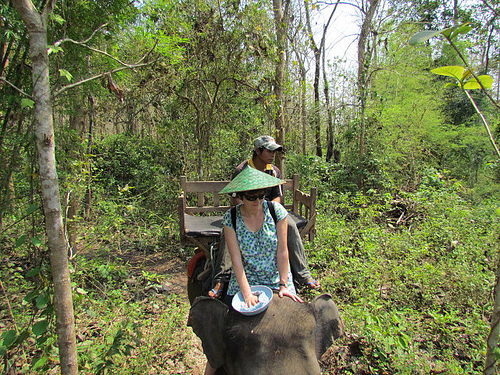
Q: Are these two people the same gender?
A: No, they are both male and female.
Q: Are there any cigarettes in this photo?
A: No, there are no cigarettes.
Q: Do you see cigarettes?
A: No, there are no cigarettes.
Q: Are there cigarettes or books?
A: No, there are no cigarettes or books.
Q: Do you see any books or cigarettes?
A: No, there are no cigarettes or books.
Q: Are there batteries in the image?
A: No, there are no batteries.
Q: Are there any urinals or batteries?
A: No, there are no batteries or urinals.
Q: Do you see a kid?
A: No, there are no children.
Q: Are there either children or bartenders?
A: No, there are no children or bartenders.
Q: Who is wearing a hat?
A: The man is wearing a hat.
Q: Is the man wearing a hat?
A: Yes, the man is wearing a hat.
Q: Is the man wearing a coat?
A: No, the man is wearing a hat.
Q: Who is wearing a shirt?
A: The man is wearing a shirt.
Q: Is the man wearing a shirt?
A: Yes, the man is wearing a shirt.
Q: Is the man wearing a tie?
A: No, the man is wearing a shirt.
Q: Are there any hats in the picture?
A: Yes, there is a hat.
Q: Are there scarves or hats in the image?
A: Yes, there is a hat.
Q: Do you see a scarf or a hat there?
A: Yes, there is a hat.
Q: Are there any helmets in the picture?
A: No, there are no helmets.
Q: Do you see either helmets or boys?
A: No, there are no helmets or boys.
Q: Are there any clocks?
A: No, there are no clocks.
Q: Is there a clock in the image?
A: No, there are no clocks.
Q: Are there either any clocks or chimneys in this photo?
A: No, there are no clocks or chimneys.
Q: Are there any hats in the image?
A: Yes, there is a hat.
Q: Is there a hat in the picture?
A: Yes, there is a hat.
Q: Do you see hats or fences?
A: Yes, there is a hat.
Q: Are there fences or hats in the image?
A: Yes, there is a hat.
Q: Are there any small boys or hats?
A: Yes, there is a small hat.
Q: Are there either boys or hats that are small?
A: Yes, the hat is small.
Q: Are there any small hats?
A: Yes, there is a small hat.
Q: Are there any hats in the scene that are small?
A: Yes, there is a hat that is small.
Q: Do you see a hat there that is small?
A: Yes, there is a hat that is small.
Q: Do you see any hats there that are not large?
A: Yes, there is a small hat.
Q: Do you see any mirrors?
A: No, there are no mirrors.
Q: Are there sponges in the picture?
A: No, there are no sponges.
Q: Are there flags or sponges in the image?
A: No, there are no sponges or flags.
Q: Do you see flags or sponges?
A: No, there are no sponges or flags.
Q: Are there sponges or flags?
A: No, there are no sponges or flags.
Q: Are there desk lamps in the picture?
A: No, there are no desk lamps.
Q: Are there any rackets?
A: No, there are no rackets.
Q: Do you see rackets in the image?
A: No, there are no rackets.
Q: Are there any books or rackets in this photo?
A: No, there are no rackets or books.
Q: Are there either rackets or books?
A: No, there are no rackets or books.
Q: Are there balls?
A: No, there are no balls.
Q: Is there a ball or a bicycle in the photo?
A: No, there are no balls or bicycles.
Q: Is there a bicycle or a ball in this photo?
A: No, there are no balls or bicycles.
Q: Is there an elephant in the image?
A: Yes, there is an elephant.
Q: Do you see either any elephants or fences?
A: Yes, there is an elephant.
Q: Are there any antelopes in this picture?
A: No, there are no antelopes.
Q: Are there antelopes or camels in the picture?
A: No, there are no antelopes or camels.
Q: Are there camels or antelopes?
A: No, there are no antelopes or camels.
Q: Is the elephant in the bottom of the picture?
A: Yes, the elephant is in the bottom of the image.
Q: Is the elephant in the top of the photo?
A: No, the elephant is in the bottom of the image.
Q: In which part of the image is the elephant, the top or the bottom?
A: The elephant is in the bottom of the image.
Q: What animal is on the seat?
A: The elephant is on the seat.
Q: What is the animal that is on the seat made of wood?
A: The animal is an elephant.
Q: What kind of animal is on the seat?
A: The animal is an elephant.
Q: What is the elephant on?
A: The elephant is on the seat.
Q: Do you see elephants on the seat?
A: Yes, there is an elephant on the seat.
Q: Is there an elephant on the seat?
A: Yes, there is an elephant on the seat.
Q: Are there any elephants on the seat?
A: Yes, there is an elephant on the seat.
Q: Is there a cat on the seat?
A: No, there is an elephant on the seat.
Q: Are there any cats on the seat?
A: No, there is an elephant on the seat.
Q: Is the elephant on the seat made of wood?
A: Yes, the elephant is on the seat.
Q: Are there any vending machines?
A: No, there are no vending machines.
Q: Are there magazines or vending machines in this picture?
A: No, there are no vending machines or magazines.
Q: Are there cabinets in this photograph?
A: No, there are no cabinets.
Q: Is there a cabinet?
A: No, there are no cabinets.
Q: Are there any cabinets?
A: No, there are no cabinets.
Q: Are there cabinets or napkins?
A: No, there are no cabinets or napkins.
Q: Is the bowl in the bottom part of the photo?
A: Yes, the bowl is in the bottom of the image.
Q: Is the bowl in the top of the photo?
A: No, the bowl is in the bottom of the image.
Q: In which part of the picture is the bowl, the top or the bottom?
A: The bowl is in the bottom of the image.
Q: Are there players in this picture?
A: No, there are no players.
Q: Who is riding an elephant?
A: The lady is riding an elephant.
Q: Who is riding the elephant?
A: The lady is riding an elephant.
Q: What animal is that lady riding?
A: The lady is riding an elephant.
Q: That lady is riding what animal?
A: The lady is riding an elephant.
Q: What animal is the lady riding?
A: The lady is riding an elephant.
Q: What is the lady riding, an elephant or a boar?
A: The lady is riding an elephant.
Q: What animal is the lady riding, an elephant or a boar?
A: The lady is riding an elephant.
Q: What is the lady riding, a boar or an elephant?
A: The lady is riding an elephant.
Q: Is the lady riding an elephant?
A: Yes, the lady is riding an elephant.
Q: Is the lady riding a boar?
A: No, the lady is riding an elephant.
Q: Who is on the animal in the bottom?
A: The lady is on the elephant.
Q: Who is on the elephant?
A: The lady is on the elephant.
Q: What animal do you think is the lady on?
A: The lady is on the elephant.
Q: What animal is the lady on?
A: The lady is on the elephant.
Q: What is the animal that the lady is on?
A: The animal is an elephant.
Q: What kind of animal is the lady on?
A: The lady is on the elephant.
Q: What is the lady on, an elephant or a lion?
A: The lady is on an elephant.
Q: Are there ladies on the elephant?
A: Yes, there is a lady on the elephant.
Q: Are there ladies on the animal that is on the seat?
A: Yes, there is a lady on the elephant.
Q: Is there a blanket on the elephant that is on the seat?
A: No, there is a lady on the elephant.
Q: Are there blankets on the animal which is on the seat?
A: No, there is a lady on the elephant.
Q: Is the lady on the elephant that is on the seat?
A: Yes, the lady is on the elephant.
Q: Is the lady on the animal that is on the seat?
A: Yes, the lady is on the elephant.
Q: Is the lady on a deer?
A: No, the lady is on the elephant.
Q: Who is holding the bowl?
A: The lady is holding the bowl.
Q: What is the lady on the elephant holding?
A: The lady is holding the bowl.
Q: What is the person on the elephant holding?
A: The lady is holding the bowl.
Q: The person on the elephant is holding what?
A: The lady is holding the bowl.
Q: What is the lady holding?
A: The lady is holding the bowl.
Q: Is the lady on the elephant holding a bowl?
A: Yes, the lady is holding a bowl.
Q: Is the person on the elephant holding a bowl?
A: Yes, the lady is holding a bowl.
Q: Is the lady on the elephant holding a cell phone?
A: No, the lady is holding a bowl.